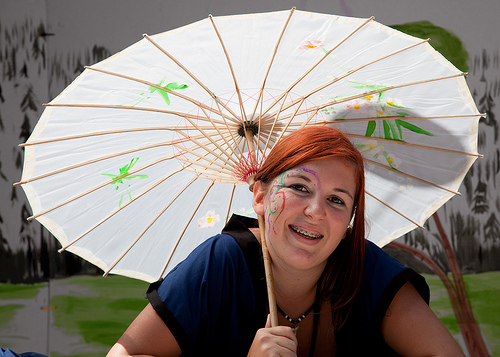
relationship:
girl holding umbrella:
[103, 127, 467, 355] [12, 5, 487, 327]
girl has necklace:
[103, 127, 467, 355] [268, 296, 323, 335]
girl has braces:
[103, 127, 467, 355] [288, 225, 323, 241]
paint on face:
[266, 165, 319, 236] [254, 153, 356, 268]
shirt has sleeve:
[145, 214, 431, 356] [146, 233, 232, 356]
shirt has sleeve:
[145, 214, 431, 356] [358, 237, 430, 356]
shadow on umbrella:
[328, 102, 468, 188] [12, 5, 487, 327]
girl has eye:
[103, 127, 467, 355] [290, 182, 313, 193]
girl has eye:
[103, 127, 467, 355] [326, 193, 345, 206]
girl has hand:
[103, 127, 467, 355] [245, 312, 297, 356]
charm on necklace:
[293, 327, 301, 338] [268, 296, 323, 335]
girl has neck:
[103, 127, 467, 355] [266, 232, 330, 301]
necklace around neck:
[268, 296, 323, 335] [266, 232, 330, 301]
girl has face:
[103, 127, 467, 355] [254, 153, 356, 268]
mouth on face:
[288, 222, 326, 244] [254, 153, 356, 268]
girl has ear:
[103, 127, 467, 355] [252, 179, 268, 215]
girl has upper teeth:
[103, 127, 467, 355] [290, 224, 324, 237]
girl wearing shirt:
[103, 127, 467, 355] [145, 214, 431, 356]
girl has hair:
[103, 127, 467, 355] [255, 124, 365, 333]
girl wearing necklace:
[103, 127, 467, 355] [268, 296, 323, 335]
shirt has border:
[145, 214, 431, 356] [147, 279, 189, 356]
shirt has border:
[145, 214, 431, 356] [223, 212, 271, 329]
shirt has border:
[145, 214, 431, 356] [372, 267, 431, 353]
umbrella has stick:
[12, 5, 487, 327] [246, 130, 279, 327]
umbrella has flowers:
[12, 5, 487, 327] [350, 81, 438, 143]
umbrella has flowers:
[12, 5, 487, 327] [298, 37, 329, 56]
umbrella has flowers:
[12, 5, 487, 327] [144, 78, 188, 104]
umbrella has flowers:
[12, 5, 487, 327] [105, 160, 149, 205]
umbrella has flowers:
[12, 5, 487, 327] [192, 209, 226, 230]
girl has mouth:
[103, 127, 467, 355] [288, 222, 326, 244]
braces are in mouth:
[288, 225, 323, 241] [288, 222, 326, 244]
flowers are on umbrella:
[350, 81, 438, 143] [12, 5, 487, 327]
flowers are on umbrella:
[298, 37, 329, 56] [12, 5, 487, 327]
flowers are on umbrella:
[144, 78, 188, 104] [12, 5, 487, 327]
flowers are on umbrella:
[105, 160, 149, 205] [12, 5, 487, 327]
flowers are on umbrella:
[192, 209, 226, 230] [12, 5, 487, 327]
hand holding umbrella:
[245, 312, 297, 356] [12, 5, 487, 327]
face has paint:
[254, 153, 356, 268] [266, 165, 319, 236]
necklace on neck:
[268, 296, 323, 335] [266, 232, 330, 301]